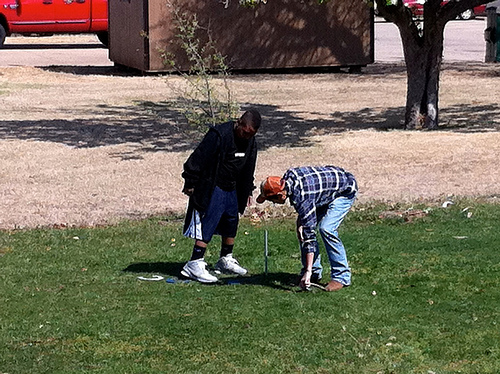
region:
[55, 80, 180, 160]
shadow of the tree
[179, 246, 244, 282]
white colour shoe of the person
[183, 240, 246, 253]
black colour socks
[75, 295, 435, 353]
a green grass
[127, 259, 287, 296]
shadow of two people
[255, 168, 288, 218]
red colour cap in man's head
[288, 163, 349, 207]
a man wearing checked shirt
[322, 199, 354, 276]
a man wearing blue jeans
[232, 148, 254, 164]
a person kept mobile in his pocket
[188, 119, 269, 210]
a man wearing black colour jacket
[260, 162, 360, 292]
Man bending over to touch the ground.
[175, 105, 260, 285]
Man looking down.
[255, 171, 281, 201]
Orange and white baseball hat.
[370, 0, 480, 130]
A tree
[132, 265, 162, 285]
A white horseshoe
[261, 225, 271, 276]
A short skinny pole in the ground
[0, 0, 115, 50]
A bright red vehicle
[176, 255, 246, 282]
White tennis shoes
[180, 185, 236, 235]
Long dark blue and white shorts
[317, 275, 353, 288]
A brown shoe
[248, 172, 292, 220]
a man wearing a orange cap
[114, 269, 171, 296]
a horse shoe on the ground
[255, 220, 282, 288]
a steak in the ground to play horse shoes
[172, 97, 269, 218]
a boy wearing a black jacket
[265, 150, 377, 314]
a man wearing blue jeans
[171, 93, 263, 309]
a boy wearing white tennis shoes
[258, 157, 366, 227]
a man wearing a plaid shirt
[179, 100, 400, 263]
two people looking down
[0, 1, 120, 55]
a red pick up truck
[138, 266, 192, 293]
two horse shoes on the ground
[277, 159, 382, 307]
man is bending over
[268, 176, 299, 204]
man has orange cap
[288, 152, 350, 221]
man has blue checked shirt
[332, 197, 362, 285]
man has blue jeans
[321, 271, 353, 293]
man has brown boots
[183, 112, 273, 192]
man on left has black coat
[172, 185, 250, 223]
man has blue and white shorts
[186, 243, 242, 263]
man has black socks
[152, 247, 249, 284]
man has white shoes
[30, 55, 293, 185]
brown dead grass behind men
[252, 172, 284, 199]
a bright orange baseball cap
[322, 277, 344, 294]
a brown leather boot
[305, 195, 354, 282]
a pair of light blue jeans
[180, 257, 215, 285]
a white high top sneaker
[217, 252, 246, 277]
a white high top sneaker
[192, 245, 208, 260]
a black sock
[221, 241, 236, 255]
a black sock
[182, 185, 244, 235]
a blue and white pair of long shorts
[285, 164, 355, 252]
a black blue and white plaid shirt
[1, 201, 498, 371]
green trimmed grass